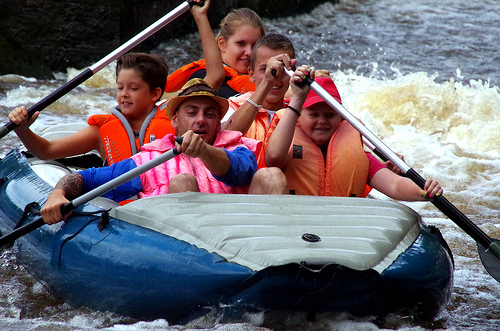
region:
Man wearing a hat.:
[164, 72, 231, 145]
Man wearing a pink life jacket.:
[127, 118, 241, 203]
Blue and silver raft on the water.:
[24, 160, 452, 314]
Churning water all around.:
[330, 10, 476, 58]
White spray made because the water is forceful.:
[387, 50, 489, 142]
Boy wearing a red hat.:
[290, 60, 340, 114]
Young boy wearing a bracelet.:
[282, 91, 299, 123]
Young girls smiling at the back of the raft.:
[215, 5, 273, 77]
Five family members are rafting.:
[61, 11, 399, 191]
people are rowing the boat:
[40, 8, 434, 295]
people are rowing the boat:
[22, 15, 397, 260]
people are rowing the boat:
[13, 17, 410, 283]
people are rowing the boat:
[14, 20, 418, 279]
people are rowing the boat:
[44, 20, 422, 245]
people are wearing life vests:
[56, 29, 406, 259]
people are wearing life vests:
[60, 5, 399, 227]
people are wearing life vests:
[40, 0, 420, 234]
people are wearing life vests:
[42, 25, 399, 257]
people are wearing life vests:
[64, 28, 389, 213]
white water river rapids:
[1, 63, 498, 329]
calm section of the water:
[95, 0, 498, 88]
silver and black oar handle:
[2, 138, 193, 247]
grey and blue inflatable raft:
[1, 123, 455, 324]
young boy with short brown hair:
[7, 0, 224, 165]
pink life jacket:
[130, 127, 263, 199]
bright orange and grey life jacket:
[86, 97, 181, 206]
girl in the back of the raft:
[164, 8, 269, 98]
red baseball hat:
[293, 73, 344, 110]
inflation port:
[299, 231, 321, 241]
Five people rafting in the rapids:
[16, 20, 464, 316]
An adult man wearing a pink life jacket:
[44, 80, 296, 224]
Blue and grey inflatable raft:
[6, 140, 458, 319]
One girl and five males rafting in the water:
[31, 8, 400, 205]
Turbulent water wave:
[310, 18, 496, 188]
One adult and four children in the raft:
[65, 5, 460, 305]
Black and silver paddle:
[272, 53, 499, 281]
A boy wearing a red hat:
[271, 70, 419, 210]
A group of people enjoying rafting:
[1, 5, 454, 303]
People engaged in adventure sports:
[21, 7, 488, 321]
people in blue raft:
[17, 15, 498, 318]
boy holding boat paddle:
[273, 46, 488, 289]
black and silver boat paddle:
[279, 51, 494, 296]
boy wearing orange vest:
[261, 106, 383, 217]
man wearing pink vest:
[134, 122, 249, 211]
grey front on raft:
[101, 157, 420, 302]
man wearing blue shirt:
[68, 134, 275, 206]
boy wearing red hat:
[278, 68, 345, 125]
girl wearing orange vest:
[158, 42, 248, 99]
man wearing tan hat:
[160, 69, 236, 126]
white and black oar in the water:
[298, 72, 498, 277]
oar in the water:
[2, 138, 183, 238]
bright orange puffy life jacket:
[252, 107, 367, 197]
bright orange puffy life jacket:
[87, 107, 172, 162]